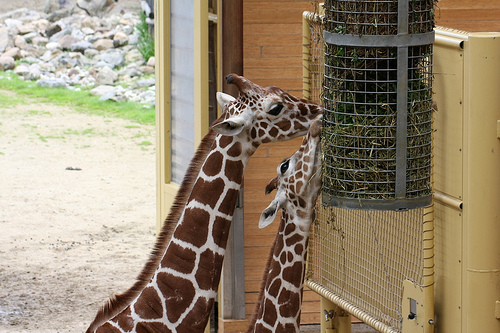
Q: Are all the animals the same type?
A: Yes, all the animals are giraffes.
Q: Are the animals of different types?
A: No, all the animals are giraffes.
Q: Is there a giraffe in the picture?
A: Yes, there is a giraffe.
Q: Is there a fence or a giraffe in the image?
A: Yes, there is a giraffe.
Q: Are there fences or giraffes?
A: Yes, there is a giraffe.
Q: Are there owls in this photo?
A: No, there are no owls.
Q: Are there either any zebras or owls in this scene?
A: No, there are no owls or zebras.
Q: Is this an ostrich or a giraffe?
A: This is a giraffe.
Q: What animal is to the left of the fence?
A: The animal is a giraffe.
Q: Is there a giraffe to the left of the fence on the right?
A: Yes, there is a giraffe to the left of the fence.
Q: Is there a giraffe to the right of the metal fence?
A: No, the giraffe is to the left of the fence.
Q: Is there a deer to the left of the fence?
A: No, there is a giraffe to the left of the fence.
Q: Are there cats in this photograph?
A: No, there are no cats.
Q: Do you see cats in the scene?
A: No, there are no cats.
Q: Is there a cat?
A: No, there are no cats.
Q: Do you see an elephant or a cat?
A: No, there are no cats or elephants.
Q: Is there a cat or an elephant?
A: No, there are no cats or elephants.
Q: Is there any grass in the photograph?
A: Yes, there is grass.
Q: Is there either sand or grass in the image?
A: Yes, there is grass.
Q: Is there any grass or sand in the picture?
A: Yes, there is grass.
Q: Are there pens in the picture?
A: No, there are no pens.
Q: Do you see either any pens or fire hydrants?
A: No, there are no pens or fire hydrants.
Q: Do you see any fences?
A: Yes, there is a fence.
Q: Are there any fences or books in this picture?
A: Yes, there is a fence.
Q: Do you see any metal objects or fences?
A: Yes, there is a metal fence.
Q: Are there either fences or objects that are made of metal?
A: Yes, the fence is made of metal.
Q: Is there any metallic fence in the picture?
A: Yes, there is a metal fence.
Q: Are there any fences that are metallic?
A: Yes, there is a fence that is metallic.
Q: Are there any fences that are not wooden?
A: Yes, there is a metallic fence.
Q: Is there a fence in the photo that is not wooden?
A: Yes, there is a metallic fence.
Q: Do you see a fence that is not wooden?
A: Yes, there is a metallic fence.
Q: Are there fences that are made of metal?
A: Yes, there is a fence that is made of metal.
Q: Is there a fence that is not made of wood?
A: Yes, there is a fence that is made of metal.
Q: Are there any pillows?
A: No, there are no pillows.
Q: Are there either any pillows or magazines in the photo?
A: No, there are no pillows or magazines.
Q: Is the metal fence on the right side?
A: Yes, the fence is on the right of the image.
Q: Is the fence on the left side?
A: No, the fence is on the right of the image.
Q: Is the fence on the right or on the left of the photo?
A: The fence is on the right of the image.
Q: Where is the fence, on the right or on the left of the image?
A: The fence is on the right of the image.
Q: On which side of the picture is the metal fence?
A: The fence is on the right of the image.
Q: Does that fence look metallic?
A: Yes, the fence is metallic.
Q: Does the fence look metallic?
A: Yes, the fence is metallic.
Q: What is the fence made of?
A: The fence is made of metal.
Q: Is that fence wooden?
A: No, the fence is metallic.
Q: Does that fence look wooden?
A: No, the fence is metallic.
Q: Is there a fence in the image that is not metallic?
A: No, there is a fence but it is metallic.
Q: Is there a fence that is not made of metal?
A: No, there is a fence but it is made of metal.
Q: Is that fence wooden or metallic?
A: The fence is metallic.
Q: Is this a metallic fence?
A: Yes, this is a metallic fence.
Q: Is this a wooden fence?
A: No, this is a metallic fence.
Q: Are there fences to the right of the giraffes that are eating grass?
A: Yes, there is a fence to the right of the giraffes.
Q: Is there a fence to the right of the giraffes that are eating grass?
A: Yes, there is a fence to the right of the giraffes.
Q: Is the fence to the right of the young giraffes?
A: Yes, the fence is to the right of the giraffes.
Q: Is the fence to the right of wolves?
A: No, the fence is to the right of the giraffes.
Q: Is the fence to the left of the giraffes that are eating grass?
A: No, the fence is to the right of the giraffes.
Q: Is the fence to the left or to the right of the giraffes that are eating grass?
A: The fence is to the right of the giraffes.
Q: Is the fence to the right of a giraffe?
A: Yes, the fence is to the right of a giraffe.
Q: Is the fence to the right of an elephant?
A: No, the fence is to the right of a giraffe.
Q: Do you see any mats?
A: No, there are no mats.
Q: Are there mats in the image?
A: No, there are no mats.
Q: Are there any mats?
A: No, there are no mats.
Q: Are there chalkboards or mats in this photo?
A: No, there are no mats or chalkboards.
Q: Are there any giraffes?
A: Yes, there are giraffes.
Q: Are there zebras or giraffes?
A: Yes, there are giraffes.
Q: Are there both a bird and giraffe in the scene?
A: No, there are giraffes but no birds.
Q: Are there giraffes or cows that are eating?
A: Yes, the giraffes are eating.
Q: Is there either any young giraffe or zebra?
A: Yes, there are young giraffes.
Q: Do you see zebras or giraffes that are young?
A: Yes, the giraffes are young.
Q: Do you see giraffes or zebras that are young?
A: Yes, the giraffes are young.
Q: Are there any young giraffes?
A: Yes, there are young giraffes.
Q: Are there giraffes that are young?
A: Yes, there are giraffes that are young.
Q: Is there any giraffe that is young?
A: Yes, there are giraffes that are young.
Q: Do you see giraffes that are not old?
A: Yes, there are young giraffes.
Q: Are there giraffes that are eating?
A: Yes, there are giraffes that are eating.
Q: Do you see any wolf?
A: No, there are no wolves.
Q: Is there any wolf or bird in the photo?
A: No, there are no wolves or birds.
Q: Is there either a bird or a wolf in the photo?
A: No, there are no wolves or birds.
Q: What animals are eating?
A: The animals are giraffes.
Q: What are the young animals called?
A: The animals are giraffes.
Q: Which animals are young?
A: The animals are giraffes.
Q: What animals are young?
A: The animals are giraffes.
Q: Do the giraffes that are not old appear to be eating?
A: Yes, the giraffes are eating.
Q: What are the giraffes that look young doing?
A: The giraffes are eating.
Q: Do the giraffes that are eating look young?
A: Yes, the giraffes are young.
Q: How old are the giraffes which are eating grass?
A: The giraffes are young.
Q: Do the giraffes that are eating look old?
A: No, the giraffes are young.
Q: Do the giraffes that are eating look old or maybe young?
A: The giraffes are young.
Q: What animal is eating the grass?
A: The giraffes are eating the grass.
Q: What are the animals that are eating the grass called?
A: The animals are giraffes.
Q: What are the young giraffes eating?
A: The giraffes are eating grass.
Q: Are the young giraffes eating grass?
A: Yes, the giraffes are eating grass.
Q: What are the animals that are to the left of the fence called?
A: The animals are giraffes.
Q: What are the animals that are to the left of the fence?
A: The animals are giraffes.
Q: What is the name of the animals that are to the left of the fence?
A: The animals are giraffes.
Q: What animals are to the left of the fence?
A: The animals are giraffes.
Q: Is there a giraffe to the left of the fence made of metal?
A: Yes, there are giraffes to the left of the fence.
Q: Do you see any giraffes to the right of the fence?
A: No, the giraffes are to the left of the fence.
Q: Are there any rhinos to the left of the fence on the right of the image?
A: No, there are giraffes to the left of the fence.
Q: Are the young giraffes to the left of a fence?
A: Yes, the giraffes are to the left of a fence.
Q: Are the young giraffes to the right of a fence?
A: No, the giraffes are to the left of a fence.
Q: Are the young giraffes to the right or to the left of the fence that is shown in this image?
A: The giraffes are to the left of the fence.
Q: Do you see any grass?
A: Yes, there is grass.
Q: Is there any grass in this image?
A: Yes, there is grass.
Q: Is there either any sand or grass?
A: Yes, there is grass.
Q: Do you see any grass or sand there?
A: Yes, there is grass.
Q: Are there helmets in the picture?
A: No, there are no helmets.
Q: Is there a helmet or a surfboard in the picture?
A: No, there are no helmets or surfboards.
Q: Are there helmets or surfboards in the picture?
A: No, there are no helmets or surfboards.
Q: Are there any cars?
A: No, there are no cars.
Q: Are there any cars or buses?
A: No, there are no cars or buses.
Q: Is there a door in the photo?
A: Yes, there is a door.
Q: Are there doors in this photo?
A: Yes, there is a door.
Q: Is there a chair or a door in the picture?
A: Yes, there is a door.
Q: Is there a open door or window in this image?
A: Yes, there is an open door.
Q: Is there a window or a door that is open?
A: Yes, the door is open.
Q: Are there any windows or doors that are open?
A: Yes, the door is open.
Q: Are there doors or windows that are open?
A: Yes, the door is open.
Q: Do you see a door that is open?
A: Yes, there is an open door.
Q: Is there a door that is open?
A: Yes, there is a door that is open.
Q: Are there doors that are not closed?
A: Yes, there is a open door.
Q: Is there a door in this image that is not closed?
A: Yes, there is a open door.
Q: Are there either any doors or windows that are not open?
A: No, there is a door but it is open.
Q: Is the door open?
A: Yes, the door is open.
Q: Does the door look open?
A: Yes, the door is open.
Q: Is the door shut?
A: No, the door is open.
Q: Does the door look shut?
A: No, the door is open.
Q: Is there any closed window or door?
A: No, there is a door but it is open.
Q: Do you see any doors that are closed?
A: No, there is a door but it is open.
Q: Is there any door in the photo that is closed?
A: No, there is a door but it is open.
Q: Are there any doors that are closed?
A: No, there is a door but it is open.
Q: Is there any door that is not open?
A: No, there is a door but it is open.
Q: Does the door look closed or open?
A: The door is open.